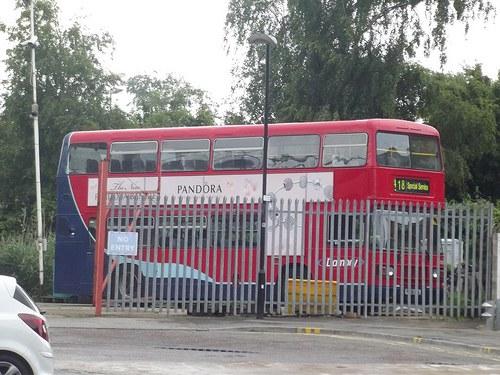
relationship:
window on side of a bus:
[161, 139, 212, 174] [54, 118, 446, 316]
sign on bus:
[85, 172, 335, 204] [54, 118, 446, 316]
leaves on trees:
[449, 152, 459, 172] [388, 56, 498, 221]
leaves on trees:
[457, 122, 477, 142] [388, 56, 498, 221]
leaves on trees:
[349, 44, 367, 64] [249, 1, 481, 118]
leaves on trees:
[360, 80, 376, 94] [249, 1, 481, 118]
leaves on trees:
[307, 89, 322, 99] [249, 1, 481, 118]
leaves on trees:
[61, 87, 199, 126] [113, 65, 215, 125]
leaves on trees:
[61, 87, 199, 126] [0, 3, 124, 218]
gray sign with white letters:
[105, 234, 150, 260] [110, 230, 130, 247]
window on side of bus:
[320, 128, 359, 167] [56, 129, 459, 366]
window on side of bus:
[209, 134, 263, 170] [54, 118, 446, 316]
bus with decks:
[54, 118, 446, 316] [93, 132, 443, 193]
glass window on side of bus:
[264, 133, 316, 164] [52, 117, 453, 234]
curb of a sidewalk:
[250, 324, 360, 336] [264, 319, 494, 350]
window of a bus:
[370, 202, 444, 256] [54, 118, 446, 316]